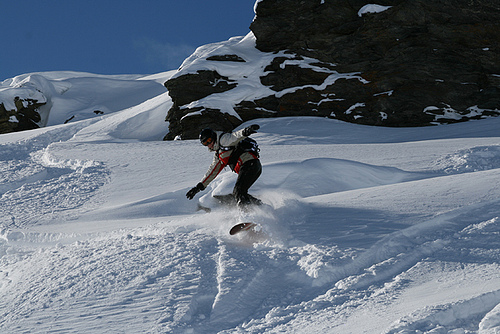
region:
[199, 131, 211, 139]
The black helmet the snowboarder is wearing.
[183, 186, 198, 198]
The glove on the snowboarder's left hand.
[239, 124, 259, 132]
The glove on the snowboarder's right hand.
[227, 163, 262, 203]
The pants the snowboarder is wearing.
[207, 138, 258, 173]
The coat the snowboarder is wearing.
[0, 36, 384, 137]
The snow on the mountain.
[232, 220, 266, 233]
The snowboard the person is riding.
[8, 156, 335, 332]
The tracks in the snow.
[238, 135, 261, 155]
The back pack the snowboarder is carrying.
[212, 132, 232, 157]
The straps of the back pack.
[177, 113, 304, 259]
A snowboarder heading down a slope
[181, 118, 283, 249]
A snowboarder heading down a slope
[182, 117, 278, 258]
A snowboarder heading down a slope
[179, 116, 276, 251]
A snowboarder heading down a slope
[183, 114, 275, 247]
A snowboarder heading down a slope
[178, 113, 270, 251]
A snowboarder heading down a slope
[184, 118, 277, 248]
A snowboarder heading down a slope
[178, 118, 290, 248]
A snowboarder heading down a slope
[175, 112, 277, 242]
A snowboarder heading down a slope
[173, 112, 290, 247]
A person is snowboarding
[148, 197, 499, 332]
Tracks are in the snow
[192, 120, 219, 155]
Person is wearing a helmet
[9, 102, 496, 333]
Snow is covering the ground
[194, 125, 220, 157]
Person is wearing goggles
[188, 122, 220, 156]
The goggles are orange in color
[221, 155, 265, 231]
Person is wearing black pants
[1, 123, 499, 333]
The snow is white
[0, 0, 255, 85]
The sky is clear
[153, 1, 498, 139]
A large stone in the background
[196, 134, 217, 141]
The snow goggles the snowboarder is wearing.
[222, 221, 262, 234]
The snowboard the snowboarder is riding.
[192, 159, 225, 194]
The left arm of the snowboarder.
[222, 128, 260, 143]
The right arm of the snowboarder.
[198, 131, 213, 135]
The black helmet.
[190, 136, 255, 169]
The coat the snowboarder is wearing.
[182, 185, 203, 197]
The glove on the snowboarder's left hand.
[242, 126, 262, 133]
The glove on the snowboarder's right hand.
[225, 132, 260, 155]
The back pack the snowboarder is carrying.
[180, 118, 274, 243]
Person snowboarding down mountain.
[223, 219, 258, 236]
Tip of person's snowboard.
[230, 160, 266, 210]
Person dressed in black pants.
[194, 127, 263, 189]
Person dressed in white and red jacket.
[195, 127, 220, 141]
Person wearing black helmet.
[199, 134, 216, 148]
Person wearing goggles over eyes.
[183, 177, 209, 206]
Person wearing black glove on hand.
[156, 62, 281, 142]
Exposed moutain under snow.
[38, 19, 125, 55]
A clear blue sky over mountain.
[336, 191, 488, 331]
Snowboard tracks in snow.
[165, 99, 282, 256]
man snowboarding in the mountains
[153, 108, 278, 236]
man wearing a black helmet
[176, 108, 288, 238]
man wearing tan jacket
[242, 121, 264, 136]
The glove on the left hand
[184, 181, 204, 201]
the right hand is gloved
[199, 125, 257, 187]
The jacket on the man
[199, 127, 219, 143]
The black helmet on the man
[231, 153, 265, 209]
The black pants on the man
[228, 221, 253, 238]
The snowboard in the snow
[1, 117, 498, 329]
The slope is snowy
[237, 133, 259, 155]
The backpack on the man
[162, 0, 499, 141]
The rocky cliff behind the man